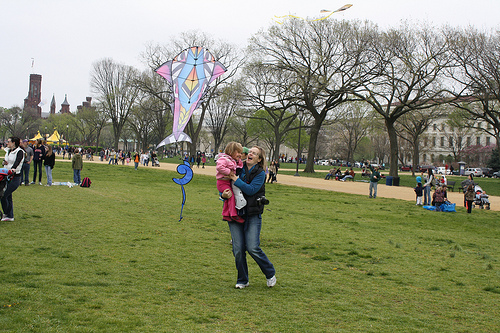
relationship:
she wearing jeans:
[196, 164, 284, 333] [219, 201, 282, 333]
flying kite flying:
[153, 42, 227, 150] [145, 99, 229, 296]